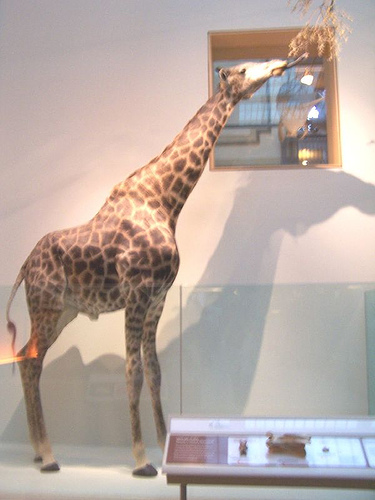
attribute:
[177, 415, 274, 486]
sign — small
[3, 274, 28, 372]
tail — medium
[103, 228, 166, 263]
spots — brown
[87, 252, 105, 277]
spot — brown, orange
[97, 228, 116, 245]
spot — brown, orange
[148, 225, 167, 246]
spot — brown, orange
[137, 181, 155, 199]
spot — brown, orange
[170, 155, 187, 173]
spot — brown, orange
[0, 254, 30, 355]
tail — thin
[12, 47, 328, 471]
giraffe — tall, brown, tan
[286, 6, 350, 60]
branch — small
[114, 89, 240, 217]
neck — long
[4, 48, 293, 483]
giraffe — spotted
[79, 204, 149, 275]
fur — long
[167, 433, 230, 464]
brown sign — information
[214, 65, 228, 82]
ears — dark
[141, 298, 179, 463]
leg — light brown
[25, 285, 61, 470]
leg — light brown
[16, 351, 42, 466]
leg — light brown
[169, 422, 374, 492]
sign — informational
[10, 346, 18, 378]
hair — small, brown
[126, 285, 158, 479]
leg — light brown